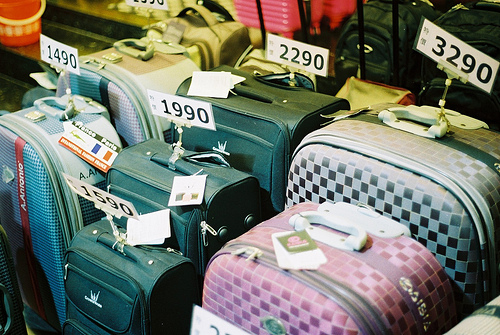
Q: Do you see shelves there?
A: No, there are no shelves.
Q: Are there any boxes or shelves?
A: No, there are no shelves or boxes.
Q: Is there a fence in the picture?
A: No, there are no fences.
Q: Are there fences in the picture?
A: No, there are no fences.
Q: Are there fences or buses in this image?
A: No, there are no fences or buses.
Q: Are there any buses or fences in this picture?
A: No, there are no fences or buses.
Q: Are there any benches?
A: No, there are no benches.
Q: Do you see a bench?
A: No, there are no benches.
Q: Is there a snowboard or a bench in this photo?
A: No, there are no benches or snowboards.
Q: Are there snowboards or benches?
A: No, there are no benches or snowboards.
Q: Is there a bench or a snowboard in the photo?
A: No, there are no benches or snowboards.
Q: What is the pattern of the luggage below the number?
A: The luggage is checkered.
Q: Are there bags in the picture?
A: Yes, there is a bag.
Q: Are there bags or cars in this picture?
A: Yes, there is a bag.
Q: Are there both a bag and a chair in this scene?
A: No, there is a bag but no chairs.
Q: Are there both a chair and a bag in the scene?
A: No, there is a bag but no chairs.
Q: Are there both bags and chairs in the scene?
A: No, there is a bag but no chairs.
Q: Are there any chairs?
A: No, there are no chairs.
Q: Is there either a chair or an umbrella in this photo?
A: No, there are no chairs or umbrellas.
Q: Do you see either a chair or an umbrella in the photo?
A: No, there are no chairs or umbrellas.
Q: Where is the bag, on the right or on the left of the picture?
A: The bag is on the left of the image.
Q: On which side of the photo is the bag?
A: The bag is on the left of the image.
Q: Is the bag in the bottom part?
A: Yes, the bag is in the bottom of the image.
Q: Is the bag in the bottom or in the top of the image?
A: The bag is in the bottom of the image.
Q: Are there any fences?
A: No, there are no fences.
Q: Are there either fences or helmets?
A: No, there are no fences or helmets.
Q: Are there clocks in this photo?
A: No, there are no clocks.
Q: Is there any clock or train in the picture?
A: No, there are no clocks or trains.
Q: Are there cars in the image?
A: No, there are no cars.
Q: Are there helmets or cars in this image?
A: No, there are no cars or helmets.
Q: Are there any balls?
A: No, there are no balls.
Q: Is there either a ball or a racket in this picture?
A: No, there are no balls or rackets.